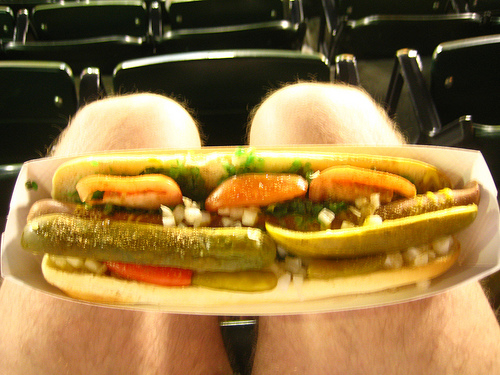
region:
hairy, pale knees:
[40, 66, 413, 142]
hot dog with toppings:
[2, 148, 494, 304]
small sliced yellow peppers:
[69, 165, 422, 210]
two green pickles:
[6, 205, 488, 270]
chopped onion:
[162, 191, 226, 225]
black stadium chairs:
[5, 1, 495, 138]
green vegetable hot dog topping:
[143, 138, 340, 178]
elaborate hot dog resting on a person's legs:
[5, 58, 496, 359]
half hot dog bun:
[25, 246, 497, 313]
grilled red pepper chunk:
[72, 244, 199, 286]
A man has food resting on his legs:
[0, 89, 499, 364]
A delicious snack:
[11, 153, 496, 307]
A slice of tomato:
[203, 168, 309, 213]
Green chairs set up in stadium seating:
[3, 3, 498, 77]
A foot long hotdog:
[28, 193, 487, 234]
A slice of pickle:
[21, 215, 276, 277]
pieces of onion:
[391, 243, 455, 270]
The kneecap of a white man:
[63, 85, 203, 145]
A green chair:
[388, 34, 498, 150]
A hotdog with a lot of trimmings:
[7, 148, 499, 308]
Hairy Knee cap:
[273, 88, 360, 122]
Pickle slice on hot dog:
[52, 222, 227, 259]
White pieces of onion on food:
[166, 211, 235, 222]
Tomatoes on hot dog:
[211, 184, 325, 206]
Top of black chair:
[141, 54, 260, 81]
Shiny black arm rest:
[393, 49, 440, 134]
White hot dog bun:
[58, 269, 150, 304]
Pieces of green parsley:
[173, 165, 245, 182]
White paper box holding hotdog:
[13, 155, 56, 290]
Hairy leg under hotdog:
[277, 322, 484, 374]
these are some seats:
[28, 5, 367, 89]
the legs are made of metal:
[400, 48, 437, 127]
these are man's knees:
[76, 85, 388, 141]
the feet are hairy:
[56, 82, 405, 139]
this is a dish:
[476, 237, 493, 266]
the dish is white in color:
[466, 234, 499, 269]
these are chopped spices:
[168, 204, 397, 223]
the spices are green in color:
[178, 172, 207, 194]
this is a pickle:
[26, 216, 265, 271]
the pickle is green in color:
[77, 222, 173, 261]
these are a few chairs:
[46, 17, 488, 83]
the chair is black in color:
[199, 65, 236, 107]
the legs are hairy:
[50, 87, 427, 129]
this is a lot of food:
[11, 141, 494, 305]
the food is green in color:
[13, 218, 253, 267]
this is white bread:
[67, 279, 149, 303]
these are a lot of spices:
[163, 203, 313, 220]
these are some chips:
[202, 170, 409, 199]